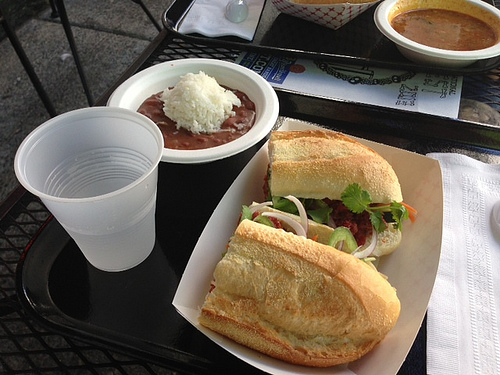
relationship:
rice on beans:
[158, 67, 239, 132] [128, 82, 261, 158]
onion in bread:
[263, 211, 308, 241] [196, 216, 403, 371]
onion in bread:
[281, 187, 311, 236] [196, 216, 403, 371]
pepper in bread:
[321, 220, 362, 256] [196, 216, 403, 371]